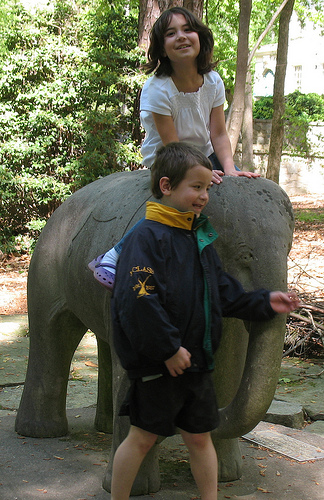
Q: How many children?
A: Two.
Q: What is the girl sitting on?
A: Elephant.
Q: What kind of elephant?
A: Statue.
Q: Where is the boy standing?
A: Beside elephant.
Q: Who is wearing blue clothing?
A: Boy.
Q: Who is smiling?
A: The children.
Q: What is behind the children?
A: Trees.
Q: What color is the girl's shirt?
A: White.